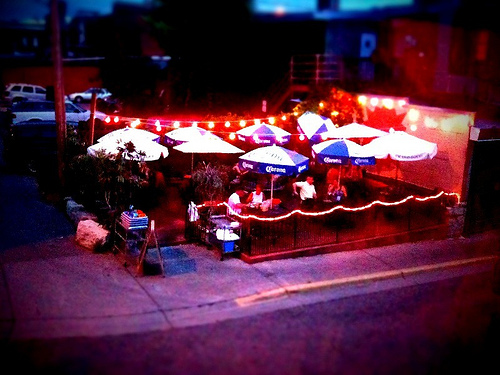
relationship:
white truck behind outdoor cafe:
[13, 101, 110, 125] [84, 95, 479, 280]